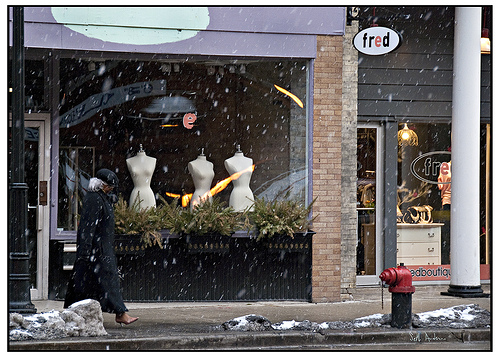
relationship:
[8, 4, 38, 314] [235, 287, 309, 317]
lamp post on sidewalk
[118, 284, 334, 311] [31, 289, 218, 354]
snow on sidewalk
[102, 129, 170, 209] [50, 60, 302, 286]
mannequins in window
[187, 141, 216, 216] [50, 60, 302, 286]
mannequins in window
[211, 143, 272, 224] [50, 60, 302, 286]
mannequins in window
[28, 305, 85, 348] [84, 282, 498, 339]
snow on sidewalk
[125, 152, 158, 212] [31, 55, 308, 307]
mannequins in storefront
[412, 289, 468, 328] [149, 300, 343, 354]
snow on sidewalk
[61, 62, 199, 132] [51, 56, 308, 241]
reflection in display window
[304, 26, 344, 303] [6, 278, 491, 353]
wall facing sidewalk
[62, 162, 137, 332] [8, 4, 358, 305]
woman walking by boutique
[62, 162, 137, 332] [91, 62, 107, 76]
woman in snow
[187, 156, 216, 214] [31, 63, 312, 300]
mannequins in display window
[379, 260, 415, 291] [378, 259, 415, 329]
top on fire hydrant